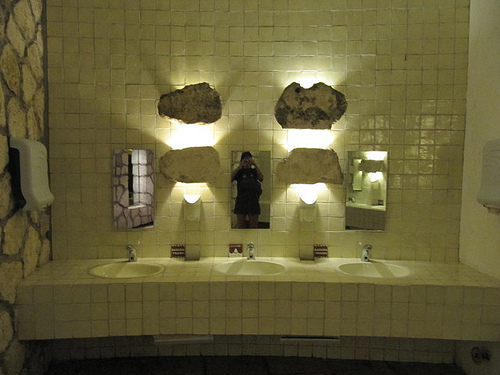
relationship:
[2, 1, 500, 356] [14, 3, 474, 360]
wall has tiles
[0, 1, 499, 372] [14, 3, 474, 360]
bathroom has tiles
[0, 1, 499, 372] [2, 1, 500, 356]
bathroom has wall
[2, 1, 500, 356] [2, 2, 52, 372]
wall has rock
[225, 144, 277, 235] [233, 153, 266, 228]
mirror has reflection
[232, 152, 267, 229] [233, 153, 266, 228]
camera man in reflection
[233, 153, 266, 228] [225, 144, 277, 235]
reflection in mirror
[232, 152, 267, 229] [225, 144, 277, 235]
camera man in mirror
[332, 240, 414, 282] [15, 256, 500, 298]
sink on countertop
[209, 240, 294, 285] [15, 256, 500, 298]
sink on countertop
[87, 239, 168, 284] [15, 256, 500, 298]
sink on countertop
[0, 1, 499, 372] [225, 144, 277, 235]
bathroom has mirror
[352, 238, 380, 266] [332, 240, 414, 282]
faucet above sink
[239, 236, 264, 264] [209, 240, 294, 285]
faucet above sink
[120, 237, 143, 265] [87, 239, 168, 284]
faucet above sink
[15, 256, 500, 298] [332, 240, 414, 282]
countertop has sink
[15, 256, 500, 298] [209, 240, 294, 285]
countertop has sink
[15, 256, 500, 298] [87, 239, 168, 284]
countertop has sink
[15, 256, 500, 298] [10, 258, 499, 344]
countertop has tile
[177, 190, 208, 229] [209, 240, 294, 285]
light fixture above sink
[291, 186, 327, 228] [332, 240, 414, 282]
light fixture above sink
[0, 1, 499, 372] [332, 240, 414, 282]
bathroom has sink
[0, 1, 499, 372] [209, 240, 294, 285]
bathroom has sink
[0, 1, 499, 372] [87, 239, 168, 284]
bathroom has sink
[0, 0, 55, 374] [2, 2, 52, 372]
wall has rock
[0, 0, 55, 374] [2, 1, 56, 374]
wall has rocks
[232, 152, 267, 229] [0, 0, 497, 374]
camera man taking photo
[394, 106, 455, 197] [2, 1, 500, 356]
light reflection on wall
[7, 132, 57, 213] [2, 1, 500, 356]
towel dispenser on wall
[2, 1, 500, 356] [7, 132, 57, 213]
wall has towel dispenser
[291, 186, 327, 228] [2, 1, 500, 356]
light fixture shining on wall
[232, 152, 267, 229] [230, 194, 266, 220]
camera man wearing shorts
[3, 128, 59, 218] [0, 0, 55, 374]
towel dispenser on wall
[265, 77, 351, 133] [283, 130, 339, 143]
rock has lights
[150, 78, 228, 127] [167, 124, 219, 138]
rock has lights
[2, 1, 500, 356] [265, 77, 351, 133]
wall has rock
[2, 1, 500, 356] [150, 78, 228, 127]
wall has rock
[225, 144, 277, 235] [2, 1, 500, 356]
mirror on wall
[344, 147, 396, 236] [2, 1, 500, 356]
mirror on wall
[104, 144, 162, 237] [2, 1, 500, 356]
mirror on wall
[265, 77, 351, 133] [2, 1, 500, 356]
rock on wall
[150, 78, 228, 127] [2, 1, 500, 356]
rock on wall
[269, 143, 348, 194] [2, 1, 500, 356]
rock on wall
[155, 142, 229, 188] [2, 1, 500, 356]
rock on wall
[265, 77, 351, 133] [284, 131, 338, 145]
rock has light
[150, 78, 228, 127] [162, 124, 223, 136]
rock has light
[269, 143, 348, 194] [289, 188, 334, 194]
rock has light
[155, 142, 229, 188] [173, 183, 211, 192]
rock has light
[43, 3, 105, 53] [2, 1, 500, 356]
part of wall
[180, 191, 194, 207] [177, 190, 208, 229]
part of light fixture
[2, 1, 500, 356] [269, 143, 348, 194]
wall has rock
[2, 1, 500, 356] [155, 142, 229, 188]
wall has rock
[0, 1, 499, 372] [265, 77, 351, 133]
bathroom has rock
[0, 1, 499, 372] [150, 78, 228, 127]
bathroom has rock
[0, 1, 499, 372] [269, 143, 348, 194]
bathroom has rock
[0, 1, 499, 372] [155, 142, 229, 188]
bathroom has rock